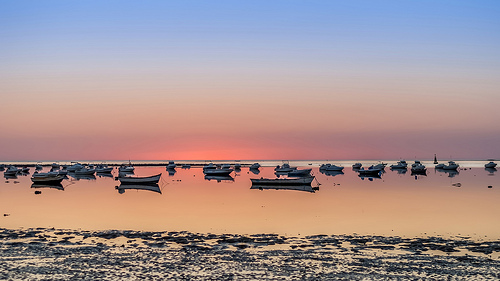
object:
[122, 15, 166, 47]
sky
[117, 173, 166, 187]
boats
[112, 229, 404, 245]
beach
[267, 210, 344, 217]
water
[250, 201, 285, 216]
ocean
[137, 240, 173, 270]
ground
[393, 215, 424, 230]
reflection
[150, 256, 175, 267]
sand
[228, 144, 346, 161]
evening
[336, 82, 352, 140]
colors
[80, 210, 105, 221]
surface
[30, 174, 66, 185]
boat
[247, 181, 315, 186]
bottom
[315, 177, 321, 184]
part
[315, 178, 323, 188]
string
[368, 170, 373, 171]
edge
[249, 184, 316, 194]
shadow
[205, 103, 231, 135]
rays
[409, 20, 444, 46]
no clouds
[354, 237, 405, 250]
land